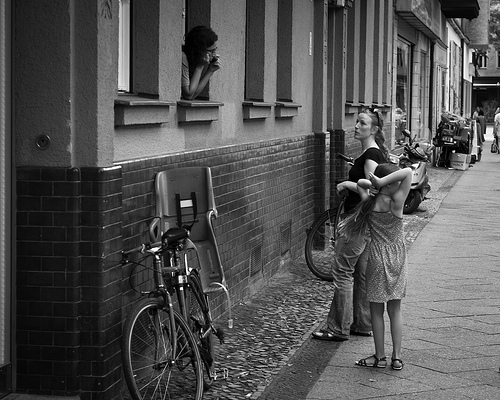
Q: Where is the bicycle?
A: Leaning against an outside wall.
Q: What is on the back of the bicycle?
A: A seat for a child.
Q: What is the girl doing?
A: Holding her arms behind her head.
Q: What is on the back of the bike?
A: A car seat.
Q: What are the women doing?
A: Talking.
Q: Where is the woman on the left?
A: In the window.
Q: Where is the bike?
A: Leaning against the building.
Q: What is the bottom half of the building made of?
A: Brick.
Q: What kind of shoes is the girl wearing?
A: Sandals.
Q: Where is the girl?
A: Standing by the woman.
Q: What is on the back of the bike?
A: A child's seat.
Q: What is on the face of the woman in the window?
A: Glasses.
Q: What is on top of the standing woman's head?
A: Sunglasses.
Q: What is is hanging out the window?
A: The woman.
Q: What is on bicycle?
A: Child seat.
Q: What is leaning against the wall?
A: Bicycle.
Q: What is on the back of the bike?
A: Child's seat.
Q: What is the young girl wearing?
A: Dress.